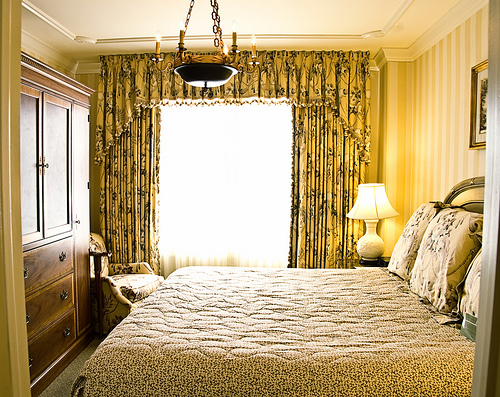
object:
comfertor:
[70, 265, 478, 395]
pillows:
[459, 249, 483, 345]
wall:
[405, 8, 484, 206]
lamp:
[151, 0, 259, 88]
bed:
[68, 175, 485, 395]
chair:
[89, 232, 165, 333]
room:
[0, 0, 499, 394]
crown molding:
[22, 1, 490, 61]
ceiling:
[19, 1, 459, 60]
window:
[155, 101, 293, 278]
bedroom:
[1, 2, 499, 394]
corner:
[20, 42, 150, 343]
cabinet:
[17, 49, 98, 397]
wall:
[21, 45, 75, 78]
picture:
[476, 68, 489, 142]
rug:
[35, 343, 96, 394]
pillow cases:
[386, 200, 443, 282]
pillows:
[407, 206, 484, 316]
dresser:
[18, 50, 94, 394]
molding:
[20, 2, 488, 75]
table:
[347, 257, 393, 269]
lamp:
[345, 182, 401, 266]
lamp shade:
[345, 182, 400, 220]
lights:
[155, 30, 162, 59]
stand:
[359, 259, 386, 267]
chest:
[24, 58, 86, 390]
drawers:
[22, 234, 74, 297]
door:
[43, 91, 73, 239]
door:
[74, 103, 92, 335]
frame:
[468, 59, 487, 149]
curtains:
[93, 52, 370, 270]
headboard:
[443, 176, 485, 215]